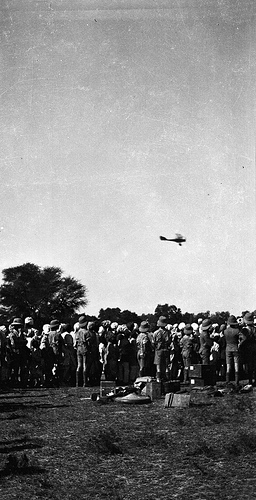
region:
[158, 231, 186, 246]
Small airplane in the sky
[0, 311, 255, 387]
Crowd of people watching an airplane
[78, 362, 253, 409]
Pile of boxes and bags on ground behind crowd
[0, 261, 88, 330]
Large leafy tree showing above heads of people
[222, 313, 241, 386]
Person standing with back to camera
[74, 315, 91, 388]
Person wearing short pants with boots or tall socks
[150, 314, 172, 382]
Person wearing shorts with suspenders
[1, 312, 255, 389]
Spectators, many wearing wide-brimmed hats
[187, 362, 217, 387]
Two square boxes with white labels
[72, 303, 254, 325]
Tops of trees showing visible over heads of spectators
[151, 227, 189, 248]
Airplane in the sky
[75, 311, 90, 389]
person in the crowd watching the airplane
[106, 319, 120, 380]
person in the crowd watching the airplane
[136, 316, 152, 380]
person in the crowd watching the airplane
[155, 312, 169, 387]
person in the crowd watching the airplane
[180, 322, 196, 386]
person in the crowd watching the airplane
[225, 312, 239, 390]
person in the crowd watching the airplane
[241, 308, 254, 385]
person in the crowd watching the airplane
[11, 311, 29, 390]
person in the crowd watching the airplane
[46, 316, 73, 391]
person in the crowd watching the airplane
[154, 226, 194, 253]
silhouette of plane in sky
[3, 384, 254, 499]
brown grass on field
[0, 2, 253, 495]
black and white photo of people in field watching plane in sky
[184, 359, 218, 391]
two black boxes on ground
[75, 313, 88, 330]
hat on person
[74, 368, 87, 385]
pair of knee high socks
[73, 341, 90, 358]
pair of shorts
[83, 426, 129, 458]
tall grass on field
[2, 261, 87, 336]
tall tree in field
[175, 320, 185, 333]
white hat on person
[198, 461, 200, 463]
part of a grass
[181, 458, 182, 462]
part of a grass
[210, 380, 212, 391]
edge of a knee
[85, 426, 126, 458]
tufts of grass on ground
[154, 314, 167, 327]
dark hat on person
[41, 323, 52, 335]
white hat on person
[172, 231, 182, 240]
plane wing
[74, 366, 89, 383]
knee high socks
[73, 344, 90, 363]
dark pair of shorts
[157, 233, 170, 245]
tail of plane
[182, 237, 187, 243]
nose of plane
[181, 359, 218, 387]
two black boxes on ground